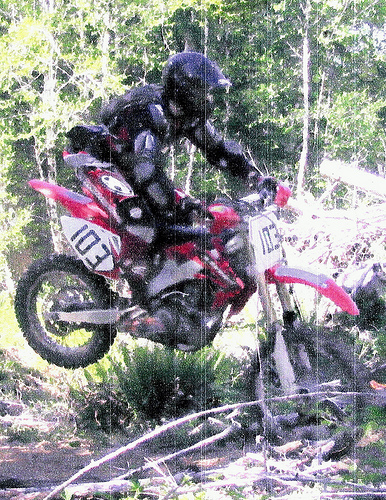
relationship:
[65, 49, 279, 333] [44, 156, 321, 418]
bike rider riding a dirt bike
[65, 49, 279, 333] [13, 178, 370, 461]
bike rider riding a dirt bike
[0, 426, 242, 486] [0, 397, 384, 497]
dirt of ground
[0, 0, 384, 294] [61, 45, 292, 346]
trees growing behind bike rider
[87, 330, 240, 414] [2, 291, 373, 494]
plant growing on ground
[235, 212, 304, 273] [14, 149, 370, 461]
numbers on white front of 103/on bike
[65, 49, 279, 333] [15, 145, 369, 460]
bike rider riding a bicycle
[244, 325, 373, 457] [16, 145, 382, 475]
front tire in a bicycle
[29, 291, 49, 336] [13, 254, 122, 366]
silver spokes in a wheel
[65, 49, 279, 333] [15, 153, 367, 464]
bike rider on bike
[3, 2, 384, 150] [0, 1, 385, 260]
leaves from trees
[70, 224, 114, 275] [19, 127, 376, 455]
black number on bike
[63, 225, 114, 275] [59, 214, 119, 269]
black number on 103/on bike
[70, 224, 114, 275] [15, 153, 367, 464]
black number on bike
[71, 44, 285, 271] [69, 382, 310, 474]
racer jumping over obstacle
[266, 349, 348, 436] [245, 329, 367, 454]
spokes of wheel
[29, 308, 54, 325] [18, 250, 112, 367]
silver spokes of wheel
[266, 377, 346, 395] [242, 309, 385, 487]
spokes of wheel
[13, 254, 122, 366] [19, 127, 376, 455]
wheel of bike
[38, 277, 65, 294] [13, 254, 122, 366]
spokes of wheel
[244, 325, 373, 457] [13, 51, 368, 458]
front tire of bike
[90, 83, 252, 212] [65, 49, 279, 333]
top of bike rider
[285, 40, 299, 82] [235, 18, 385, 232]
branches of tree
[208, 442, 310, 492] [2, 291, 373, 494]
twigs on ground